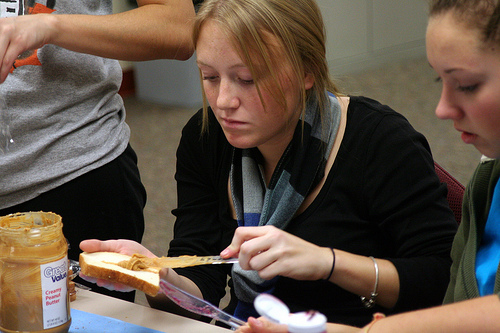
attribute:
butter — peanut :
[106, 240, 204, 302]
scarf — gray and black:
[195, 95, 368, 280]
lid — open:
[243, 285, 337, 331]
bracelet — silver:
[354, 248, 388, 320]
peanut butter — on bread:
[75, 230, 205, 306]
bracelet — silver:
[348, 237, 394, 316]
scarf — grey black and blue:
[217, 144, 339, 225]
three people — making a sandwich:
[6, 0, 484, 330]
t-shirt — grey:
[3, 3, 141, 208]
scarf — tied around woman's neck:
[206, 85, 348, 295]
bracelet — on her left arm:
[353, 246, 387, 310]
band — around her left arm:
[315, 236, 342, 293]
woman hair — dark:
[185, 2, 345, 156]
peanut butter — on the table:
[6, 199, 70, 329]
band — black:
[322, 246, 336, 282]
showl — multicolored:
[215, 86, 339, 326]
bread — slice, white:
[79, 248, 159, 292]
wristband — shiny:
[359, 254, 378, 310]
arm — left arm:
[219, 219, 398, 305]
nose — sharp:
[434, 82, 460, 119]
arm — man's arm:
[0, 2, 196, 73]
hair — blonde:
[194, 2, 336, 138]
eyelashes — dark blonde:
[199, 73, 260, 83]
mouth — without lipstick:
[217, 115, 247, 126]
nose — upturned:
[434, 82, 464, 120]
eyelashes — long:
[432, 73, 481, 91]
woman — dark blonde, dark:
[223, 0, 497, 330]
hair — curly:
[426, 0, 497, 45]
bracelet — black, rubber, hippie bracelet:
[321, 245, 333, 284]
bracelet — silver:
[360, 255, 378, 305]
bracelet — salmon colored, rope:
[367, 308, 384, 326]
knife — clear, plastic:
[157, 276, 243, 328]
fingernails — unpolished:
[220, 248, 234, 254]